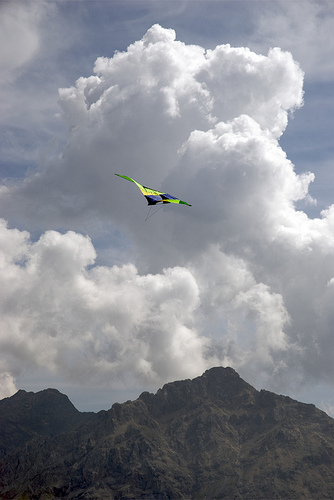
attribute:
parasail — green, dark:
[124, 170, 189, 224]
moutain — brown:
[122, 349, 249, 441]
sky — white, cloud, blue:
[44, 74, 134, 146]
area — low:
[131, 425, 260, 483]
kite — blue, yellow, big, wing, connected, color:
[107, 163, 212, 226]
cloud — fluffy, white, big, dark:
[137, 50, 189, 113]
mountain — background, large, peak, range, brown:
[22, 353, 317, 471]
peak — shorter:
[2, 347, 261, 414]